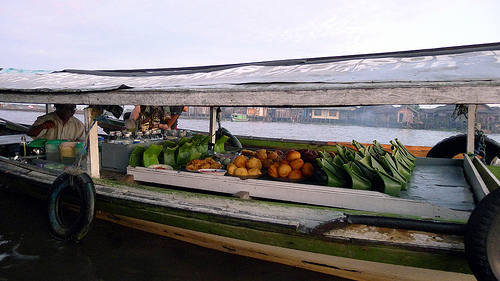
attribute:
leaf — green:
[364, 161, 410, 201]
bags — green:
[321, 139, 417, 196]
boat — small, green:
[224, 110, 251, 127]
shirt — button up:
[30, 104, 87, 141]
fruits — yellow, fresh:
[229, 149, 310, 181]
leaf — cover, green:
[351, 131, 430, 189]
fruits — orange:
[269, 145, 310, 179]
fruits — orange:
[228, 149, 265, 177]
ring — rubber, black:
[45, 171, 98, 243]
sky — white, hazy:
[183, 12, 429, 36]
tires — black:
[50, 130, 499, 277]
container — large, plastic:
[59, 141, 79, 165]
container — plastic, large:
[43, 138, 62, 169]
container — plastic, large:
[77, 139, 87, 172]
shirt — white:
[32, 112, 87, 153]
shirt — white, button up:
[36, 112, 88, 166]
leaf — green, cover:
[321, 147, 398, 193]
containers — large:
[42, 136, 88, 161]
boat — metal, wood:
[32, 58, 479, 279]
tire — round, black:
[457, 175, 499, 280]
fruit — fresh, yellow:
[239, 146, 320, 181]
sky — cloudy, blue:
[41, 17, 121, 40]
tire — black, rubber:
[35, 169, 101, 252]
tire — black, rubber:
[7, 222, 57, 269]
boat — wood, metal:
[40, 45, 330, 266]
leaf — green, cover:
[308, 103, 430, 178]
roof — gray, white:
[0, 82, 498, 111]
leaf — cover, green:
[317, 157, 349, 187]